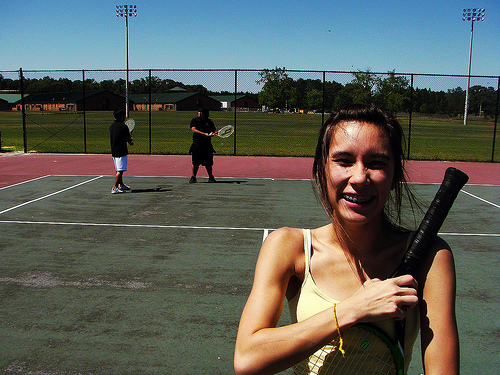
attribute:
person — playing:
[107, 109, 135, 193]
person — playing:
[188, 106, 218, 181]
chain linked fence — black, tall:
[1, 70, 498, 161]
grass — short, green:
[1, 110, 499, 161]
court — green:
[1, 174, 498, 374]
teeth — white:
[340, 192, 378, 204]